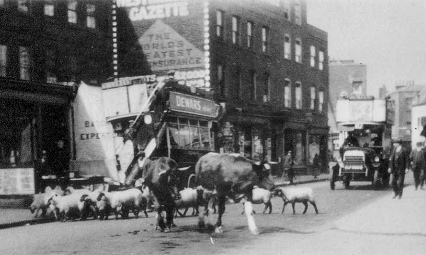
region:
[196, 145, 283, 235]
a steer in the street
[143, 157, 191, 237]
a steer in the street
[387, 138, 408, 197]
a man is standing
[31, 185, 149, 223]
a grouping of animals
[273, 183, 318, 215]
a sheep is walking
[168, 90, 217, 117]
a sign for dewars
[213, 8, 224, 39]
window on the exterior of a building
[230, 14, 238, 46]
window on the exterior of a building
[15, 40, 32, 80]
window on the exterior of a building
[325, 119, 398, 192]
a car is driving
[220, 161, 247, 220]
part of a chest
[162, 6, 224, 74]
edge of a building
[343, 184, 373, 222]
prt of a line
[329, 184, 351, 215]
part of a road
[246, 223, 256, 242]
part of a hoof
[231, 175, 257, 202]
part of a chest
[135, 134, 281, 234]
cows on the street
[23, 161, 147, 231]
sheep on the street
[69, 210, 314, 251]
street where vehicles travel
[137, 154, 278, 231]
cow in the street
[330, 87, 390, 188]
truck in the street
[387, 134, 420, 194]
people in the street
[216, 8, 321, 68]
windows in the building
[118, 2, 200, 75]
image on side of building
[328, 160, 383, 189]
tires on the truck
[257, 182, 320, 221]
animals crossing the street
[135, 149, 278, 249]
two cow crossing the road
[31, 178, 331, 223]
a herd of sheep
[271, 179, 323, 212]
black and white sheep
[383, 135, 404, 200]
person walking down the road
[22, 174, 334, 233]
sheep crossing the road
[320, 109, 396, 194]
large vehicle on the road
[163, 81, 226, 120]
sign on the building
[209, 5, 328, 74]
row of windows on the top of the building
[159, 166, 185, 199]
head is slightly bent down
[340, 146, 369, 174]
vent on the front of the vehicle